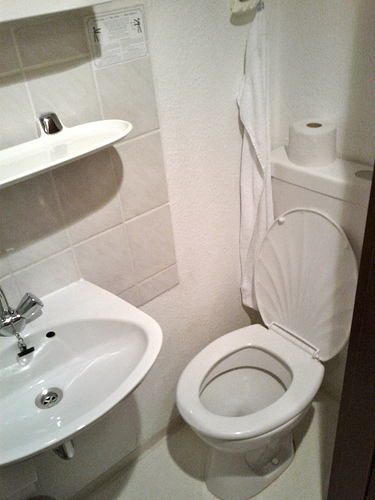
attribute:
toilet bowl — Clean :
[175, 323, 325, 455]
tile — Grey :
[124, 201, 176, 286]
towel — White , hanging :
[235, 8, 274, 312]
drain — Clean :
[33, 386, 63, 409]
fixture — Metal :
[39, 112, 64, 135]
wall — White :
[0, 0, 265, 498]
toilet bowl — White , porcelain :
[176, 322, 326, 498]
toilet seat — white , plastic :
[174, 206, 358, 440]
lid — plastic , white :
[252, 207, 359, 363]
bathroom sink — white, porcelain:
[2, 299, 182, 427]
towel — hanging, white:
[226, 10, 290, 297]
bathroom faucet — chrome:
[0, 297, 61, 331]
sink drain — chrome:
[31, 387, 69, 408]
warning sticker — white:
[89, 19, 164, 64]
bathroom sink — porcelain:
[2, 299, 163, 433]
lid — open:
[234, 209, 364, 361]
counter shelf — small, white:
[1, 97, 169, 195]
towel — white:
[226, 41, 288, 329]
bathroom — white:
[11, 35, 366, 484]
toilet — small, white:
[153, 213, 354, 469]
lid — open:
[249, 202, 356, 360]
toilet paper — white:
[295, 139, 325, 153]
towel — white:
[233, 43, 286, 294]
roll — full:
[301, 119, 319, 131]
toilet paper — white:
[288, 135, 341, 167]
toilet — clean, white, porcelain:
[157, 216, 338, 445]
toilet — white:
[190, 233, 346, 490]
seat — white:
[193, 329, 306, 437]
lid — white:
[246, 210, 363, 360]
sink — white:
[1, 300, 184, 435]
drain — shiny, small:
[12, 382, 91, 421]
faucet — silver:
[1, 299, 41, 344]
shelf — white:
[1, 107, 146, 203]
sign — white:
[82, 28, 150, 90]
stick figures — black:
[87, 9, 133, 90]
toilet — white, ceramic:
[164, 213, 333, 481]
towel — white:
[215, 28, 280, 311]